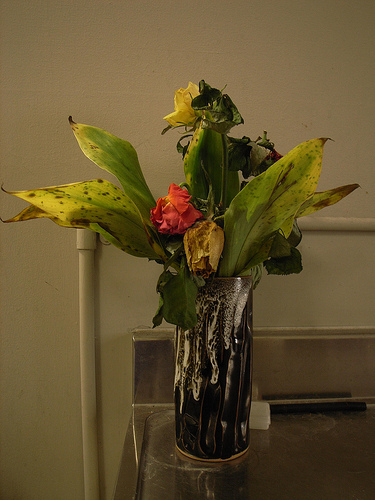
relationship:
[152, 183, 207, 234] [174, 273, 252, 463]
rose in vase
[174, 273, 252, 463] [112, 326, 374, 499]
vase on table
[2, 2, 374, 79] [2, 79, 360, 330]
wall behind flower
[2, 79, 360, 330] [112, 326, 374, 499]
flower on table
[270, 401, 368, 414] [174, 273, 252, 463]
object behind vase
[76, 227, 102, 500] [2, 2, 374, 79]
pipe on wall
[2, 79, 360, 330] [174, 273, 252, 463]
flower in vase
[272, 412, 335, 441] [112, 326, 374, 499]
residue on table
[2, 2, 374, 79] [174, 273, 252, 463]
wall behind vase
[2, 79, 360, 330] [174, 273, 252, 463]
plant in vase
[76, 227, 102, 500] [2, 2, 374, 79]
pipe behind wall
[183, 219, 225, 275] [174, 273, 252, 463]
rose in vase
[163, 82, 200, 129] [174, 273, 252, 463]
rose in vase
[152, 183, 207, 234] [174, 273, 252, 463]
flower in vase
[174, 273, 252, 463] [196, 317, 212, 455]
vase has stripes